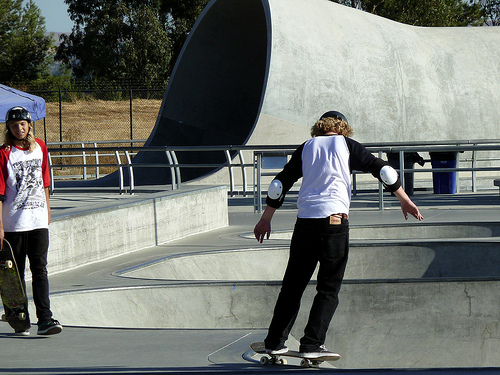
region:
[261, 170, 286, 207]
The white elbow pad on the person's left arm.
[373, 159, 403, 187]
The white elbow pad on the person's right arm.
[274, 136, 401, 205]
The black and white shirt the skateboarder is wearing.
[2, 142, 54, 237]
The white and red shirt the boy on the left is wearing.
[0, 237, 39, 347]
The skateboard being held up by the skater on the left.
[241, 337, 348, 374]
The skateboard the skateboarder is standing on.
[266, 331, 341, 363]
The black and white sneakers the skateboard is standing on.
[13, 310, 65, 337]
The black and white sneakers the skateboarder in the white and red shirt has on.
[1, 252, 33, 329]
The wheels of the skateboard the kid in the red and white shirt is holding up.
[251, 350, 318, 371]
The wheels on the skateboard the skateboarder is standing on.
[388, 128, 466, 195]
two people behind metal rails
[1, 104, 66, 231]
girl wears white shirt with red sleeves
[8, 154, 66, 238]
white shirt with black design in front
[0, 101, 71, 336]
girl holds skateboard in right hand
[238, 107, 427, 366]
man rides silver skateboard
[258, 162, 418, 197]
man wears white elbow pads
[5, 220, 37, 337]
skateboard rests atop right sneaker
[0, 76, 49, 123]
blue awning in background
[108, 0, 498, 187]
giant metal tunnel behind rails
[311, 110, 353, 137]
curly hair pokes out under helmet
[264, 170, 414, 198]
white elbow pads on boy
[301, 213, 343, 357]
dark jeans with brown tag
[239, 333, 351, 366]
black skateboard on ramp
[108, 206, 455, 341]
concrete style skatepark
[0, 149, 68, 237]
white and red t shirt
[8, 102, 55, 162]
boy with long blonde hair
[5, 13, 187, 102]
wooded area behind park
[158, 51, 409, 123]
gray concrete tunnel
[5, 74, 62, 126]
blue umbrella at park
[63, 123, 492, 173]
silver metal guard rails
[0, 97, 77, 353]
a boy holding a skatebaord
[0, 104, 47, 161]
a boy with long blonde hair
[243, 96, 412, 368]
a boy riding a skateboard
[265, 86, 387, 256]
a boy wearing a black and white shirt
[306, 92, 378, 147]
a boy with curly hair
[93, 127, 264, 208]
metal railing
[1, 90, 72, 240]
a boy wearing a red and white shirt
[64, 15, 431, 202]
a concrete tunnel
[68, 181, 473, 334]
a concrete skateboard park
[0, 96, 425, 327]
two boys at a skate park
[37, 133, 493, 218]
A metal guardrail.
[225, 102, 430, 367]
The teenager is on a skateboard.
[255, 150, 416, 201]
Elbow pads.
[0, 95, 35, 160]
The teenager is wearing a black helmet.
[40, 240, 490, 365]
An empty concrete pool for skateboarding.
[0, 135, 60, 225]
A white, red, and black, t-shirt.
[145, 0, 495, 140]
A large concrete structure.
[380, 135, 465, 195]
Two garbage bins.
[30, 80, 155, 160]
A fence.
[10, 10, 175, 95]
Trees.